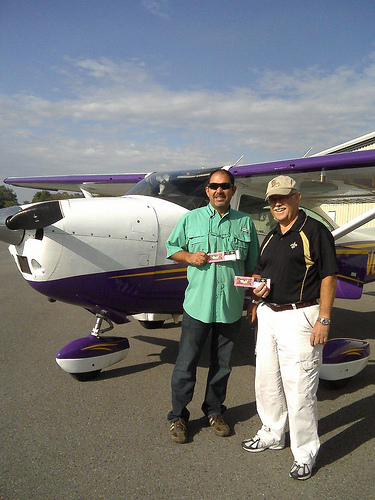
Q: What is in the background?
A: A plane.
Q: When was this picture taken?
A: Daytime.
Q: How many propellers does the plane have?
A: One.